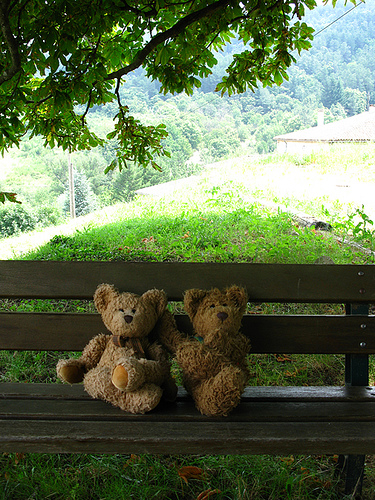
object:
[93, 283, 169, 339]
head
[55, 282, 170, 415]
teddy bear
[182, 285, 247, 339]
head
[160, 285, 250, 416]
teddy bear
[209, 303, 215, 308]
eye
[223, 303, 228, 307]
eye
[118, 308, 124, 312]
eye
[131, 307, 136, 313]
eye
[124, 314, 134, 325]
nose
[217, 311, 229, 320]
nose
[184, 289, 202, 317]
ear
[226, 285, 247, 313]
ear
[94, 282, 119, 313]
ear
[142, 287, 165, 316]
ear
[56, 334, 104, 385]
arm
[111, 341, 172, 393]
arm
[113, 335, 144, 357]
ribbon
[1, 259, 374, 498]
bench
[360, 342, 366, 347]
bolt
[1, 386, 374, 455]
seat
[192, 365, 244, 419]
legs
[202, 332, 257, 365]
arm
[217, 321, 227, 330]
mouth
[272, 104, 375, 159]
building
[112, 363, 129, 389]
foot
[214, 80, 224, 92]
leave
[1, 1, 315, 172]
tree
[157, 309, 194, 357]
arm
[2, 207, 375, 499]
grass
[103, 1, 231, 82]
limb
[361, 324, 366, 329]
bolt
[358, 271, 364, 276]
bolt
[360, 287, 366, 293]
bolt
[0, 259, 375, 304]
plank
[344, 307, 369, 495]
support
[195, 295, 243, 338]
face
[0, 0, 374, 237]
forrest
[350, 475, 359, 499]
twig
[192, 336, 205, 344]
bowtie